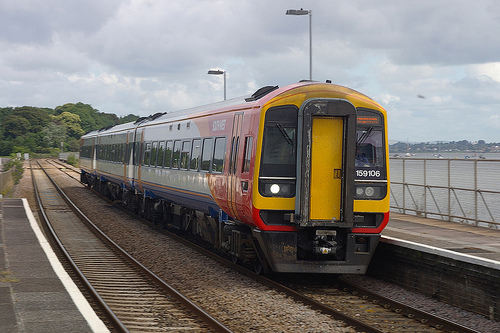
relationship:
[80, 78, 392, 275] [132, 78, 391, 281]
train has a car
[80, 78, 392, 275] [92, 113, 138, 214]
train has a car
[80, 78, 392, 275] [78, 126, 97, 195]
train has a car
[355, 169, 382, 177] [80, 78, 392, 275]
numbers are on train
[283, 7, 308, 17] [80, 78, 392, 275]
light above train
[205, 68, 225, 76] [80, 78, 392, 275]
light above train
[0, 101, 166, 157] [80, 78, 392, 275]
trees are behind train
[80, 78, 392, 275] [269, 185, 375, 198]
train has headlights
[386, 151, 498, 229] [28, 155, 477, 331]
water next to train tracks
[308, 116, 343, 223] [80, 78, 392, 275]
door on train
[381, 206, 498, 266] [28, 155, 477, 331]
walkway next to train tracks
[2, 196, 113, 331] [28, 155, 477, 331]
walkway next to train tracks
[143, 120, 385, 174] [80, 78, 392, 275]
window on train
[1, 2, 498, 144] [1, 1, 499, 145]
clouds are in sky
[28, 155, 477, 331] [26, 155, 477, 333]
train tracks has rails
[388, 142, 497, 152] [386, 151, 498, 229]
land above water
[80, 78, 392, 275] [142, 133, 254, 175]
train has windows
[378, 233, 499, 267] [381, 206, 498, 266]
line on walkway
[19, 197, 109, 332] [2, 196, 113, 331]
line on walkway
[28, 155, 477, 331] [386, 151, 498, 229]
train tracks are beside of water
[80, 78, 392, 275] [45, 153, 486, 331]
train on tracks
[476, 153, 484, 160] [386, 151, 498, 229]
boat in water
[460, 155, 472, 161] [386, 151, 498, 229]
boat in water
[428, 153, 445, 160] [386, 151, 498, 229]
boat in water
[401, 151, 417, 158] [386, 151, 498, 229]
boat in water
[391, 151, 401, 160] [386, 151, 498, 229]
boat in water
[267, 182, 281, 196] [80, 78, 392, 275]
light on train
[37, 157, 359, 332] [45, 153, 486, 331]
gravel between tracks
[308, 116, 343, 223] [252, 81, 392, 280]
door on train front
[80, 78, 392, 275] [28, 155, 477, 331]
train on train tracks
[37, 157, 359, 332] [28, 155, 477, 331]
gravel between train tracks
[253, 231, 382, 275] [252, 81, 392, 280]
plate on train front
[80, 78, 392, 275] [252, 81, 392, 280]
train has front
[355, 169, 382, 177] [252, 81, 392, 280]
numbers on train front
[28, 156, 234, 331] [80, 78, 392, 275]
track next to train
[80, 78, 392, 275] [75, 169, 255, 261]
train has bottom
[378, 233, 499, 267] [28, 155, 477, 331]
line next to train tracks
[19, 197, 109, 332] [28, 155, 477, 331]
line next to train tracks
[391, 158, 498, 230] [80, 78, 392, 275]
fence next to train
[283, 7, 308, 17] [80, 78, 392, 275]
light next to train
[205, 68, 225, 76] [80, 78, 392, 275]
light next to train